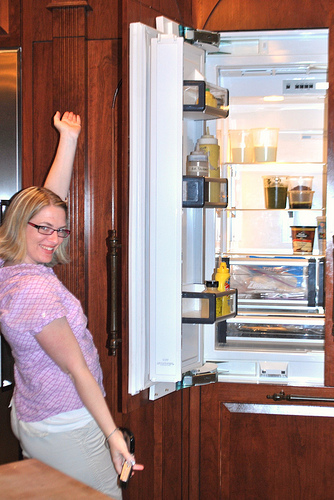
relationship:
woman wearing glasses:
[0, 106, 150, 499] [28, 221, 74, 240]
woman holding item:
[0, 106, 150, 499] [118, 458, 131, 491]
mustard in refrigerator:
[214, 259, 233, 319] [105, 14, 331, 500]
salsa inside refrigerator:
[285, 189, 315, 210] [105, 14, 331, 500]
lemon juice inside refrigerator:
[198, 85, 215, 107] [105, 14, 331, 500]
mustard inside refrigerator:
[214, 259, 233, 319] [105, 14, 331, 500]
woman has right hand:
[0, 106, 150, 499] [104, 432, 146, 481]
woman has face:
[0, 106, 150, 499] [33, 208, 71, 266]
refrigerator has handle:
[105, 14, 331, 500] [102, 227, 121, 364]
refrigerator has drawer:
[105, 14, 331, 500] [225, 255, 315, 311]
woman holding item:
[0, 106, 150, 499] [117, 460, 131, 487]